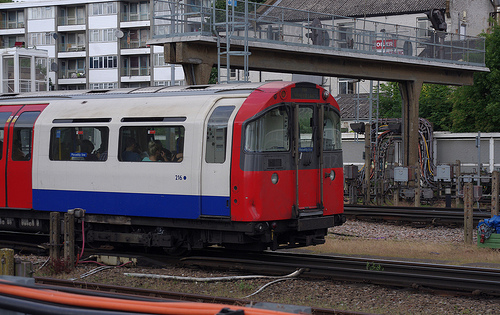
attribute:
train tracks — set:
[344, 202, 490, 228]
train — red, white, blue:
[160, 88, 349, 228]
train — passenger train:
[1, 85, 347, 246]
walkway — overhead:
[144, 4, 491, 90]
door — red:
[0, 100, 51, 212]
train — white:
[12, 92, 349, 242]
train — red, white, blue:
[0, 63, 362, 262]